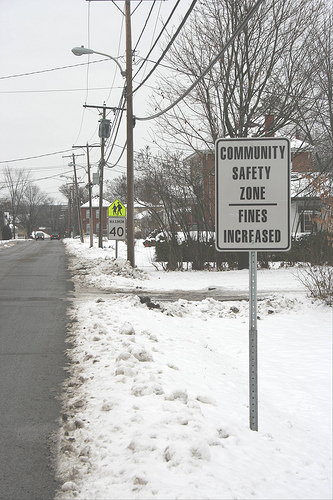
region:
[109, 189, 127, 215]
yellow and black street sign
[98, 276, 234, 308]
driveway has been shoveled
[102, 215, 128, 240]
40 on the street sign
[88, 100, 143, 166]
power lines above street sign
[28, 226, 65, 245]
cars on the road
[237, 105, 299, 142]
chimney on the house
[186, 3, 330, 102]
tree has no leaves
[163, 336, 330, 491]
street sign in the snow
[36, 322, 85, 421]
road is plowed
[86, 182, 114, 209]
snow on the roof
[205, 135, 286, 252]
sign on the pole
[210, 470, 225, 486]
patch of white snow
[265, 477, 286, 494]
patch of white snow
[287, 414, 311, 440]
patch of white snow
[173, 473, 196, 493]
patch of white snow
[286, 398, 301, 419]
patch of white snow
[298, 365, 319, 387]
patch of white snow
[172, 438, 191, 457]
patch of white snow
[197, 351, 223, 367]
patch of white snow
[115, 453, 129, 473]
patch of white snow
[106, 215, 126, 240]
Street sign that reads 40 maximum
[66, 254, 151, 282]
Dirty pile of snow along the side of a road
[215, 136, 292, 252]
Sign that reads Community Safety Zone Fines Increased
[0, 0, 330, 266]
Telephone poles with many wires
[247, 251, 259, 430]
Metal sign post sticking out of the snow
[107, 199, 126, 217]
Bright yellow sign with a picture of people walking on it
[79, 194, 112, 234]
A red brick house with snow on the roof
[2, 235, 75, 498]
Black asphalt road that is wet and shiny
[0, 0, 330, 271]
Tree branches that have no leaves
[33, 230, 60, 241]
Two distant cars facing opposite directions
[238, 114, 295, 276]
a sign on a pole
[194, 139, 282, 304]
a sign on a metal pole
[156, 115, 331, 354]
a street sign on a pole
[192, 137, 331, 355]
a street sign on a metal pole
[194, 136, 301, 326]
a pole with a sign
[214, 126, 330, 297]
a metal pole with sign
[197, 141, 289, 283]
a pole with street sign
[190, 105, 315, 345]
a metal pole with street signs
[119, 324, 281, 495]
a ground covered in snow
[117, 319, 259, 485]
snow covering the ground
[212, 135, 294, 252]
a white and black road sign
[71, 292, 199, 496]
snow on the side of the road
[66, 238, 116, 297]
snow on the side of the road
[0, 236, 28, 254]
snow on the side of the road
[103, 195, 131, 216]
a school children crossing sign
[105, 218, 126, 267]
a speed limit sign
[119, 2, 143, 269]
a wooden telephone pole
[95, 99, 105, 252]
a wooden telephone pole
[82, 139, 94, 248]
a wooden telephone pole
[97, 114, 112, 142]
a electricity transformer on a wooden pole